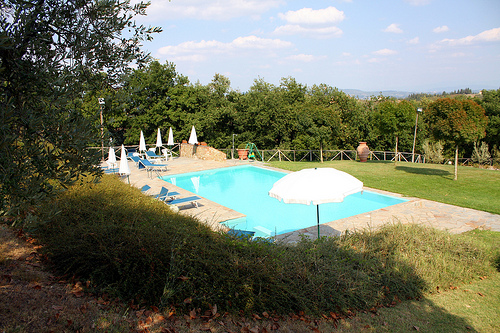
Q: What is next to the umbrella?
A: A blue pool of water.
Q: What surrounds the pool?
A: Bushes.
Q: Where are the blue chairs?
A: By the pool.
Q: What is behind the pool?
A: A line of trees.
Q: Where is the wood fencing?
A: In front of a line of trees.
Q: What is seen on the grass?
A: Shadows.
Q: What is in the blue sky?
A: White clouds.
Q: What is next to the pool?
A: An open white umbrella.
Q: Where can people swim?
A: In the pool.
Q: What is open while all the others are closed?
A: One umbrella.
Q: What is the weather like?
A: Sunny and warm.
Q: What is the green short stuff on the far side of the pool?
A: Grass.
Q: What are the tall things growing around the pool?
A: Trees.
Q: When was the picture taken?
A: Daytime.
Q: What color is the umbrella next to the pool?
A: White.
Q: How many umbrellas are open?
A: One.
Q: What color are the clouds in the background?
A: White.